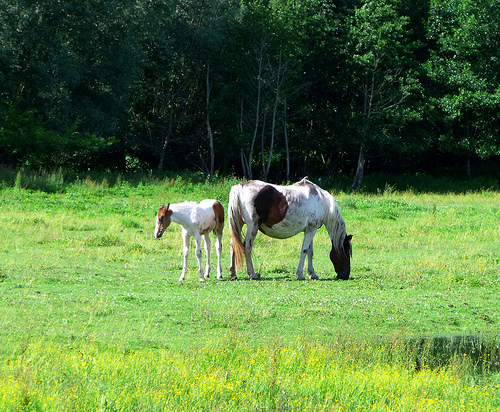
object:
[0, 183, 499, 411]
field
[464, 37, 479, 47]
leaves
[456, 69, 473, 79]
leaves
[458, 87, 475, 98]
leaves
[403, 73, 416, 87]
leaves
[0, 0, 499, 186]
tree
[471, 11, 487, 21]
leaves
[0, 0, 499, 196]
woods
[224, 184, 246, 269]
tail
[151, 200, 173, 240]
head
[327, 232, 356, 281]
head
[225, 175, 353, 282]
horse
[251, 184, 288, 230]
spot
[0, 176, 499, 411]
grass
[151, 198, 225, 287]
baby horse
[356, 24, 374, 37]
branches